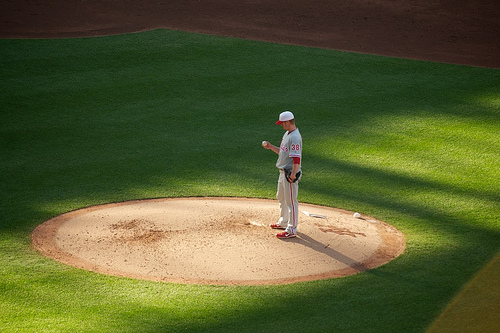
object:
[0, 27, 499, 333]
grass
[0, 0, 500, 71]
dirt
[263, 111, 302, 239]
player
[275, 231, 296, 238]
shoe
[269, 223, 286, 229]
shoe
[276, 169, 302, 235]
pants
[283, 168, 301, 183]
glove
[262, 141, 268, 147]
ball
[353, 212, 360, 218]
tissue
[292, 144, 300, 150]
number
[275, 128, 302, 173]
shirt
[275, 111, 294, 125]
hat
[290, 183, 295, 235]
stripe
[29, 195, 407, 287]
mound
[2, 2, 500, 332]
shadow